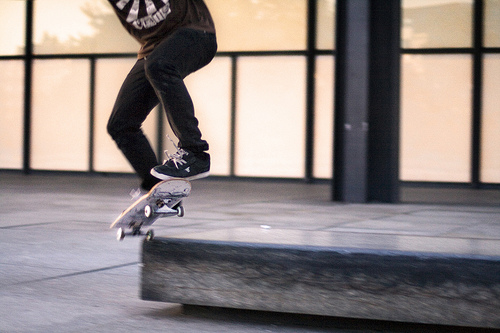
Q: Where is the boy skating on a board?
A: Inside a skateboard venue.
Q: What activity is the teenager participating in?
A: Skateboarding.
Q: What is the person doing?
A: Skateboarding.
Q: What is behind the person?
A: Windows.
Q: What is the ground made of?
A: Cement.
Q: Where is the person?
A: In the air.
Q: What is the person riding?
A: Skateboard.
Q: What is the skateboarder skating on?
A: Cement slab.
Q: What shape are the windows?
A: Rectangle.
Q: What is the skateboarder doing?
A: A trick.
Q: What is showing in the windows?
A: A reflection.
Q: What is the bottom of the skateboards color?
A: White.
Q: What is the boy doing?
A: Riding a skateboard.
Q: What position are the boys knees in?
A: Bent.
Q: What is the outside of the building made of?
A: Glass.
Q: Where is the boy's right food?
A: On the skateboard.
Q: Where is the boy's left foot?
A: Coming off of the skateboard.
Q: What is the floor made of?
A: Concrete.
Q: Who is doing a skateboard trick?
A: The boy.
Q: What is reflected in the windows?
A: Trees.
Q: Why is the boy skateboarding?
A: For fun.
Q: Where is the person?
A: In the air.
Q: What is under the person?
A: The skateboard.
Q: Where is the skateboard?
A: Under the person.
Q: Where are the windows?
A: Behind the person.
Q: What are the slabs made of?
A: Cement.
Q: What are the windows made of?
A: Glass.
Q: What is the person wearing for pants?
A: Black jeans.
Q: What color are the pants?
A: Black.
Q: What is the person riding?
A: A skateboard.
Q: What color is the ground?
A: Gray.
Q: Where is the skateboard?
A: In the air.